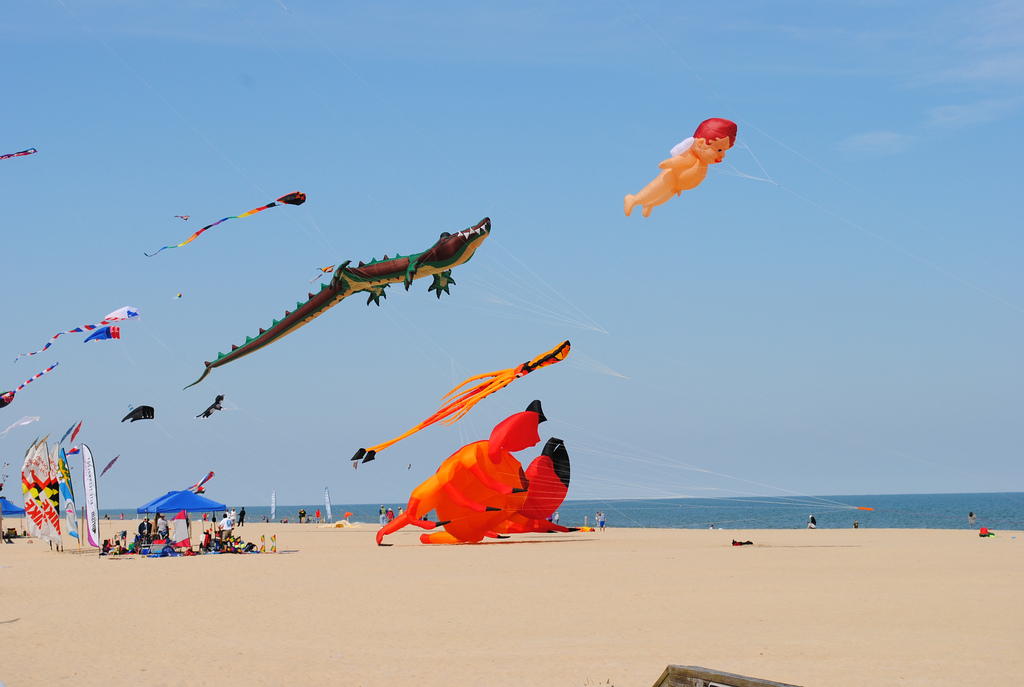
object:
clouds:
[819, 77, 1022, 171]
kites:
[0, 116, 744, 542]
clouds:
[572, 315, 655, 398]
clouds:
[723, 0, 1021, 162]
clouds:
[567, 90, 659, 171]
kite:
[377, 401, 601, 545]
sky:
[0, 0, 1024, 528]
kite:
[622, 118, 737, 221]